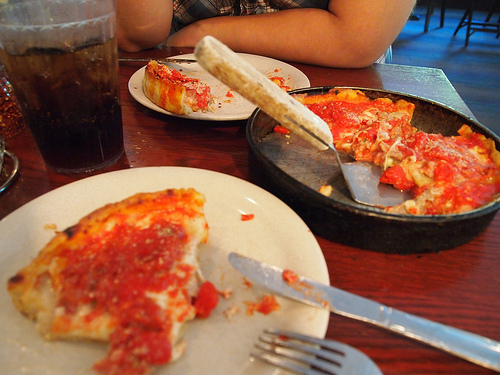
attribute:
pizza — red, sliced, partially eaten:
[291, 87, 500, 216]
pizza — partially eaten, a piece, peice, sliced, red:
[142, 60, 216, 116]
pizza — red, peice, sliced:
[7, 187, 210, 365]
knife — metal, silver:
[228, 251, 500, 373]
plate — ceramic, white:
[128, 52, 311, 121]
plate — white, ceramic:
[0, 165, 331, 374]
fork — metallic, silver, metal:
[249, 326, 384, 374]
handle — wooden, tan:
[193, 35, 334, 152]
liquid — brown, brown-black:
[0, 34, 126, 175]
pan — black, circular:
[244, 85, 499, 254]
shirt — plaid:
[170, 1, 331, 36]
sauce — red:
[58, 218, 218, 375]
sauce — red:
[306, 101, 499, 216]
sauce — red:
[153, 60, 213, 113]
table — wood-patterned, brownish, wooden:
[0, 46, 499, 374]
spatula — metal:
[193, 35, 417, 208]